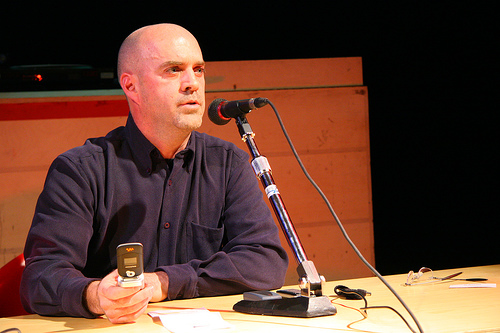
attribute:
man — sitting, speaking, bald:
[20, 22, 289, 325]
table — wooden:
[1, 265, 498, 333]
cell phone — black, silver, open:
[115, 241, 146, 289]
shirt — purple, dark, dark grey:
[19, 113, 289, 319]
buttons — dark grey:
[163, 178, 173, 231]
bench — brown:
[0, 56, 377, 286]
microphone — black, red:
[205, 95, 272, 126]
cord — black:
[255, 97, 425, 333]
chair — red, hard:
[0, 254, 33, 320]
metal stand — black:
[226, 114, 340, 319]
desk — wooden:
[1, 263, 499, 332]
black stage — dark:
[0, 0, 498, 277]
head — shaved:
[116, 20, 206, 127]